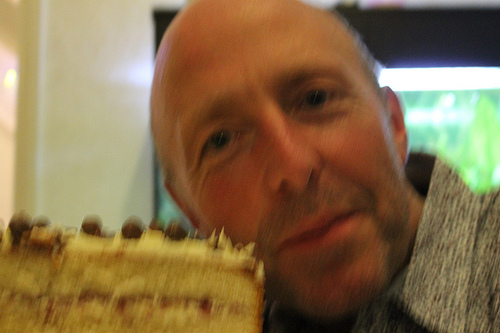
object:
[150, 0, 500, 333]
man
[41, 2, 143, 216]
wall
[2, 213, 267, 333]
cake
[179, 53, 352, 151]
crows feet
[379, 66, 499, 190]
aquarium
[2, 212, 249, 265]
topping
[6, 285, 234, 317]
filling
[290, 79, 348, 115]
eye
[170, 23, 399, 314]
face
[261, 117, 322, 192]
nose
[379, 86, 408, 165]
ear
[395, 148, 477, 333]
collar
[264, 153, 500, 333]
shirt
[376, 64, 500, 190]
tank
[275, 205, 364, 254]
lips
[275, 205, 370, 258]
mouth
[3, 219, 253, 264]
frosting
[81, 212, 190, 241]
balls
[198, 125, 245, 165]
eye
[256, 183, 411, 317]
hair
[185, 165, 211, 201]
wrinkle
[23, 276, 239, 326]
chocolate frosting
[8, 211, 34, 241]
walnut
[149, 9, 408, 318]
head